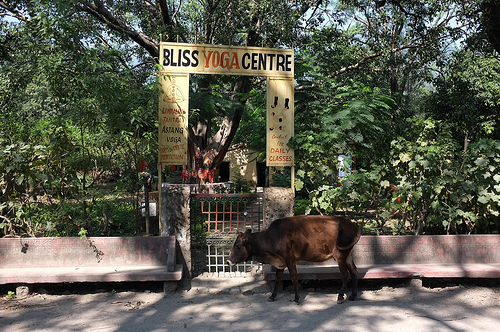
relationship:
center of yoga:
[150, 35, 301, 295] [200, 48, 242, 72]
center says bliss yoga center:
[150, 35, 301, 295] [159, 43, 298, 78]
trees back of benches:
[7, 9, 491, 226] [2, 230, 499, 297]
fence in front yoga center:
[191, 194, 236, 277] [159, 43, 298, 78]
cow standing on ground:
[224, 209, 371, 310] [0, 289, 498, 328]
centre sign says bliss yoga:
[150, 35, 301, 295] [159, 43, 298, 78]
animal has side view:
[224, 209, 371, 310] [224, 217, 267, 268]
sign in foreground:
[156, 39, 301, 173] [7, 9, 491, 226]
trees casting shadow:
[7, 9, 491, 226] [0, 289, 498, 328]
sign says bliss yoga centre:
[156, 39, 301, 173] [159, 43, 298, 78]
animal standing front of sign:
[224, 209, 371, 310] [156, 39, 301, 173]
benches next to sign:
[2, 230, 499, 297] [156, 39, 301, 173]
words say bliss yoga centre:
[159, 43, 298, 78] [156, 39, 301, 173]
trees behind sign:
[7, 9, 491, 226] [156, 39, 301, 173]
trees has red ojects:
[7, 9, 491, 226] [384, 180, 422, 212]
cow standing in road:
[224, 209, 371, 310] [0, 289, 498, 328]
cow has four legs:
[224, 209, 371, 310] [264, 258, 364, 309]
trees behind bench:
[7, 9, 491, 226] [2, 230, 499, 297]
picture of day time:
[7, 9, 491, 226] [3, 3, 497, 331]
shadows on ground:
[0, 289, 498, 328] [0, 289, 498, 328]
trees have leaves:
[7, 9, 491, 226] [347, 89, 394, 129]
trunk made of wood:
[210, 81, 251, 150] [78, 134, 94, 209]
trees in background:
[7, 9, 491, 226] [0, 3, 482, 150]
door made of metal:
[191, 194, 236, 277] [205, 219, 222, 258]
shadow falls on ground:
[0, 289, 498, 328] [0, 289, 498, 331]